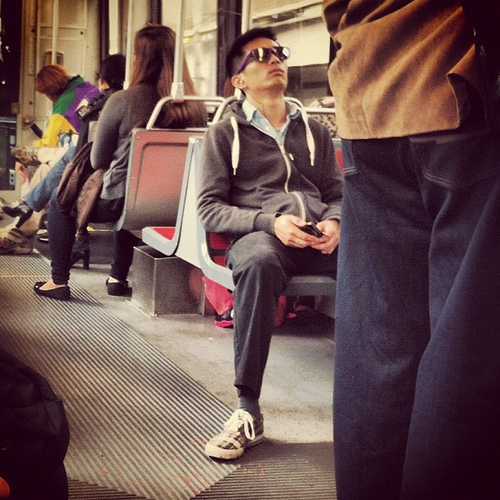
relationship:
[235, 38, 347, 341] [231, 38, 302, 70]
man in sunglasses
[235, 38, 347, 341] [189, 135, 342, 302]
man in chair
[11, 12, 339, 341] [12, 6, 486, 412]
people on train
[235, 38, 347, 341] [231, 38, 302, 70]
person wearing sunglasses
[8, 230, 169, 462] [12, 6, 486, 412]
walkway on train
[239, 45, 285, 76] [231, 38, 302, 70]
sunglasses of sunglasses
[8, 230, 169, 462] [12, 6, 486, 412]
carpet on subway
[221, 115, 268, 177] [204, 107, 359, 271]
shoestring on hoodie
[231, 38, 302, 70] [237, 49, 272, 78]
sunglasses with purple rim